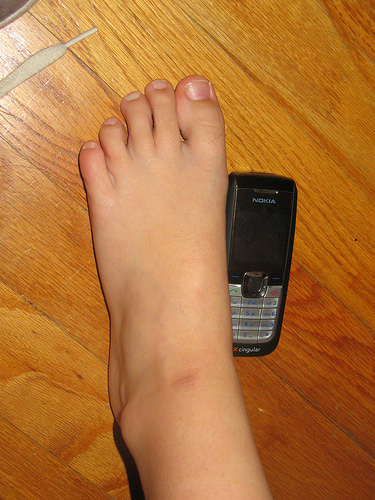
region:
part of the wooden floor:
[243, 24, 366, 157]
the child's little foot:
[81, 72, 229, 413]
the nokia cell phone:
[227, 169, 290, 355]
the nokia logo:
[251, 193, 277, 205]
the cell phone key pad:
[229, 282, 277, 343]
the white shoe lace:
[2, 24, 97, 81]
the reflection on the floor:
[1, 22, 38, 49]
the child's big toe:
[176, 75, 226, 145]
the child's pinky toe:
[78, 138, 105, 180]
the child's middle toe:
[120, 91, 156, 147]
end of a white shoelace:
[1, 27, 95, 75]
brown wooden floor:
[0, 1, 372, 496]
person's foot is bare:
[89, 78, 255, 496]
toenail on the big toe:
[182, 79, 212, 99]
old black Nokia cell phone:
[228, 168, 280, 368]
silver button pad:
[227, 281, 279, 341]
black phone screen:
[233, 197, 288, 275]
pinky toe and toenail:
[80, 141, 112, 191]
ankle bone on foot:
[115, 393, 149, 450]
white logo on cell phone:
[252, 197, 278, 206]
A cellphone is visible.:
[184, 145, 331, 476]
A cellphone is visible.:
[180, 160, 297, 341]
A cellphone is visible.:
[233, 201, 315, 354]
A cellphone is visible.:
[212, 186, 282, 381]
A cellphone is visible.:
[236, 145, 256, 299]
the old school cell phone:
[196, 190, 293, 400]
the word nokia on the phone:
[237, 182, 301, 210]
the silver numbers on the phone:
[200, 254, 291, 391]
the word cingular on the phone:
[219, 329, 300, 375]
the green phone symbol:
[219, 279, 292, 303]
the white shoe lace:
[9, 37, 161, 93]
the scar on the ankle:
[133, 350, 239, 431]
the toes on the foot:
[51, 87, 244, 198]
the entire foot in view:
[69, 73, 268, 399]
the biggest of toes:
[158, 57, 248, 173]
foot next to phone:
[62, 84, 228, 262]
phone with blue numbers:
[220, 161, 322, 378]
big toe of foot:
[177, 76, 234, 153]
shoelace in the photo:
[1, 11, 118, 105]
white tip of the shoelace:
[60, 20, 120, 67]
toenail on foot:
[181, 75, 214, 109]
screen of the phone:
[239, 199, 301, 264]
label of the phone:
[234, 184, 284, 225]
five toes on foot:
[39, 75, 222, 187]